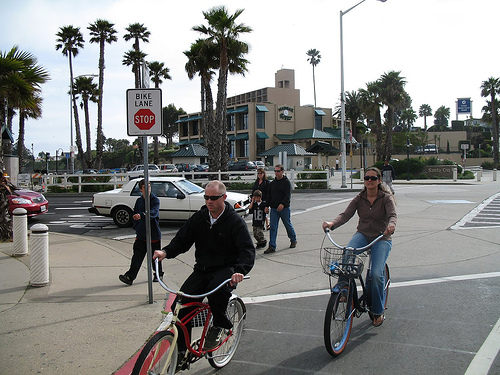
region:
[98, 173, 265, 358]
a man riding on a bicycle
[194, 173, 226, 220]
the head of an old man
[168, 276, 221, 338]
the black pants of an old man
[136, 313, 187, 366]
the front wheel of a bike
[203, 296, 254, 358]
the back wheel of a bike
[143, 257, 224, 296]
the handle of a bike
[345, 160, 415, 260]
a woman riding a bike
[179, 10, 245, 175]
a big and tall palm tree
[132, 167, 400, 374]
Two people on bikes.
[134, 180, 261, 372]
Man on a bike.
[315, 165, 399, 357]
Woman on a bike.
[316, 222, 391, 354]
Blue bike with basket on handlebars.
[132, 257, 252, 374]
A red bike.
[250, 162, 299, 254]
A family crossing the street.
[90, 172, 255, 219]
A white car stopped in the road.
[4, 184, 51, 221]
Front of a red car.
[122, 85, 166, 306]
A sign that says bike lane stop.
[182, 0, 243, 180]
Tall palm trees.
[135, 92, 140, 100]
black letter on sign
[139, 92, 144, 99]
black letter on sign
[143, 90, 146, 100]
black letter on sign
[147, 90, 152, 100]
black letter on sign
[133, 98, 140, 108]
black letter on sign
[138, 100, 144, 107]
black letter on sign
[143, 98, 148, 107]
black letter on sign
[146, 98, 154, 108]
black letter on sign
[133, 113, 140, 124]
white letter on sign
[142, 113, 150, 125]
white letter on sign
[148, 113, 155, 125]
white letter on sign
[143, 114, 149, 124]
white letter on sign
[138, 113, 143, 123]
white letter on sign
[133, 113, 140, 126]
white letter on sign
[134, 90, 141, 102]
black letter on sign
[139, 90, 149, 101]
black letter on sign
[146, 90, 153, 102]
black letter on sign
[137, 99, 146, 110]
black letter on sign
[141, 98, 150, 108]
black letter on sign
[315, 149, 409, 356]
woman riding a blue bike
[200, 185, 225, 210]
sunglasses on the man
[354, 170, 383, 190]
sunglasses on the woman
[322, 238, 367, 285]
basket on the bike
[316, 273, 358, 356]
wheel on the bike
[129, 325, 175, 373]
wheel on the bike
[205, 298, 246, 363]
wheel on the bike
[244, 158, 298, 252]
people walking in the street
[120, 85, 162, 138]
sign on a post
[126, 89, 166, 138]
large square white sign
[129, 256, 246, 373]
large metal red bike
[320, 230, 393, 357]
small metal blue bike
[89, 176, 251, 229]
small white metal car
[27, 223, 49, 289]
short white thick pole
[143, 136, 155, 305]
tall long metal pole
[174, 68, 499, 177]
large wide brown house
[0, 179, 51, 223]
short red metal car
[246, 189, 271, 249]
A person walking on a street.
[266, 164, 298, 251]
A person walking on a street.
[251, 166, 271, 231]
A person walking on a street.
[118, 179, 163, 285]
A person walking on a sidewalk.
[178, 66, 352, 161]
A building in a city.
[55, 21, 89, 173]
A tree in a city.